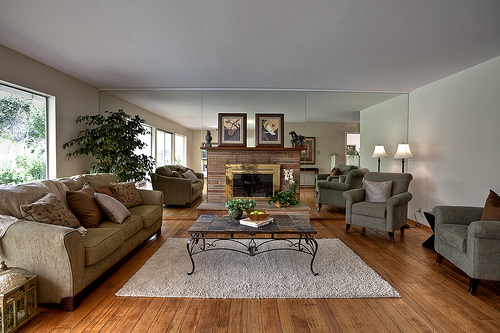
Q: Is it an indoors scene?
A: Yes, it is indoors.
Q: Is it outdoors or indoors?
A: It is indoors.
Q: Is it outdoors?
A: No, it is indoors.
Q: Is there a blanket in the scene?
A: No, there are no blankets.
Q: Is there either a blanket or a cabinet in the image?
A: No, there are no blankets or cabinets.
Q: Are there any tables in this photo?
A: Yes, there is a table.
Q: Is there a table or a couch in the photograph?
A: Yes, there is a table.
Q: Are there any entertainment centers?
A: No, there are no entertainment centers.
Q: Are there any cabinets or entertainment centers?
A: No, there are no entertainment centers or cabinets.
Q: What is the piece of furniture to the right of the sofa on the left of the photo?
A: The piece of furniture is a table.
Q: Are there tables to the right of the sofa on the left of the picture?
A: Yes, there is a table to the right of the sofa.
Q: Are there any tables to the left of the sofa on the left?
A: No, the table is to the right of the sofa.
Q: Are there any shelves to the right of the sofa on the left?
A: No, there is a table to the right of the sofa.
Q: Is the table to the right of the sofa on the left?
A: Yes, the table is to the right of the sofa.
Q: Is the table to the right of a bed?
A: No, the table is to the right of the sofa.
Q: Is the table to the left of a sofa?
A: No, the table is to the right of a sofa.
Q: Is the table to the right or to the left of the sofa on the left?
A: The table is to the right of the sofa.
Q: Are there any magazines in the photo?
A: No, there are no magazines.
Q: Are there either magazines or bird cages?
A: No, there are no magazines or bird cages.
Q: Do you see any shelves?
A: No, there are no shelves.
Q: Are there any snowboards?
A: No, there are no snowboards.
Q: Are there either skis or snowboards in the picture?
A: No, there are no snowboards or skis.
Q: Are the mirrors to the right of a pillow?
A: Yes, the mirrors are to the right of a pillow.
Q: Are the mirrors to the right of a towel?
A: No, the mirrors are to the right of a pillow.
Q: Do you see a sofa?
A: Yes, there is a sofa.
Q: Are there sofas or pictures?
A: Yes, there is a sofa.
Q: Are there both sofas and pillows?
A: Yes, there are both a sofa and a pillow.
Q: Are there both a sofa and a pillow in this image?
A: Yes, there are both a sofa and a pillow.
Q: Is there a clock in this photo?
A: No, there are no clocks.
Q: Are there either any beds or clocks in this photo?
A: No, there are no clocks or beds.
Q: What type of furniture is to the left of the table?
A: The piece of furniture is a sofa.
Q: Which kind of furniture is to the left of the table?
A: The piece of furniture is a sofa.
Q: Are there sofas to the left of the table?
A: Yes, there is a sofa to the left of the table.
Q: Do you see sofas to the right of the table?
A: No, the sofa is to the left of the table.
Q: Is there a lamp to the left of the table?
A: No, there is a sofa to the left of the table.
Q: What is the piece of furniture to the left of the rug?
A: The piece of furniture is a sofa.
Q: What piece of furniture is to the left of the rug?
A: The piece of furniture is a sofa.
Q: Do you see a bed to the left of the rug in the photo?
A: No, there is a sofa to the left of the rug.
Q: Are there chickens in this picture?
A: No, there are no chickens.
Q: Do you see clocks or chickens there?
A: No, there are no chickens or clocks.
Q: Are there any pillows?
A: Yes, there is a pillow.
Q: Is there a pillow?
A: Yes, there is a pillow.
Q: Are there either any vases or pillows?
A: Yes, there is a pillow.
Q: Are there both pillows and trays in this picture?
A: No, there is a pillow but no trays.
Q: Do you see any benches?
A: No, there are no benches.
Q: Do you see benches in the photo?
A: No, there are no benches.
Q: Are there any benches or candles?
A: No, there are no benches or candles.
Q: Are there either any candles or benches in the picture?
A: No, there are no benches or candles.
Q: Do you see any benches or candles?
A: No, there are no benches or candles.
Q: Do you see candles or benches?
A: No, there are no benches or candles.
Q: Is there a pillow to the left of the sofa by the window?
A: Yes, there is a pillow to the left of the sofa.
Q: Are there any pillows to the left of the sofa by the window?
A: Yes, there is a pillow to the left of the sofa.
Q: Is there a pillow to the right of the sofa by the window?
A: No, the pillow is to the left of the sofa.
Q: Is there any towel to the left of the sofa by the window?
A: No, there is a pillow to the left of the sofa.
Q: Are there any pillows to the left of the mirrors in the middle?
A: Yes, there is a pillow to the left of the mirrors.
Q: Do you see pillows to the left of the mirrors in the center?
A: Yes, there is a pillow to the left of the mirrors.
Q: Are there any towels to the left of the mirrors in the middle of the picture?
A: No, there is a pillow to the left of the mirrors.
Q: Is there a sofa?
A: Yes, there is a sofa.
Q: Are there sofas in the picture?
A: Yes, there is a sofa.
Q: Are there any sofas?
A: Yes, there is a sofa.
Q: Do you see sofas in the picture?
A: Yes, there is a sofa.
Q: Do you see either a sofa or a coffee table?
A: Yes, there is a sofa.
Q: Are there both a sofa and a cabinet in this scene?
A: No, there is a sofa but no cabinets.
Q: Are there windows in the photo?
A: Yes, there is a window.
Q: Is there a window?
A: Yes, there is a window.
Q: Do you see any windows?
A: Yes, there is a window.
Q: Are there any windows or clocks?
A: Yes, there is a window.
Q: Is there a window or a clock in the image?
A: Yes, there is a window.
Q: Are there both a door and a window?
A: No, there is a window but no doors.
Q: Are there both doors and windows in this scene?
A: No, there is a window but no doors.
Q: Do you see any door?
A: No, there are no doors.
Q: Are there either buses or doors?
A: No, there are no doors or buses.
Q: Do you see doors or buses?
A: No, there are no doors or buses.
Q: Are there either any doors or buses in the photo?
A: No, there are no doors or buses.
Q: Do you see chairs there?
A: Yes, there is a chair.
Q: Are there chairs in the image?
A: Yes, there is a chair.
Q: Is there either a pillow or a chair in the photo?
A: Yes, there is a chair.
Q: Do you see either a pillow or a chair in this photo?
A: Yes, there is a chair.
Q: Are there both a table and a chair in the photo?
A: Yes, there are both a chair and a table.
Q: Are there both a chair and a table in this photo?
A: Yes, there are both a chair and a table.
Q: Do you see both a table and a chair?
A: Yes, there are both a chair and a table.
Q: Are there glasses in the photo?
A: No, there are no glasses.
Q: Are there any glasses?
A: No, there are no glasses.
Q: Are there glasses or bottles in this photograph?
A: No, there are no glasses or bottles.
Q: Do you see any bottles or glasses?
A: No, there are no glasses or bottles.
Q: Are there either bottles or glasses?
A: No, there are no glasses or bottles.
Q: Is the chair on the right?
A: Yes, the chair is on the right of the image.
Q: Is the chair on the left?
A: No, the chair is on the right of the image.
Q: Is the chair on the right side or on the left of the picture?
A: The chair is on the right of the image.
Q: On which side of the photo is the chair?
A: The chair is on the right of the image.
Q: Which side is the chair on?
A: The chair is on the right of the image.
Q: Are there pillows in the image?
A: Yes, there is a pillow.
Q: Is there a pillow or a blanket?
A: Yes, there is a pillow.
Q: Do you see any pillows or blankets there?
A: Yes, there is a pillow.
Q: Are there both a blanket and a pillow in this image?
A: No, there is a pillow but no blankets.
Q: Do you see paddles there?
A: No, there are no paddles.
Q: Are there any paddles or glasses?
A: No, there are no paddles or glasses.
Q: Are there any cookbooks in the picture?
A: No, there are no cookbooks.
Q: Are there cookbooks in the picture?
A: No, there are no cookbooks.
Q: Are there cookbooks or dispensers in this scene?
A: No, there are no cookbooks or dispensers.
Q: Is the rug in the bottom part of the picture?
A: Yes, the rug is in the bottom of the image.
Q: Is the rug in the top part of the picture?
A: No, the rug is in the bottom of the image.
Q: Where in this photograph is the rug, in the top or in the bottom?
A: The rug is in the bottom of the image.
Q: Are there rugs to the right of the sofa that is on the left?
A: Yes, there is a rug to the right of the sofa.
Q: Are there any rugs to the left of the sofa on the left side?
A: No, the rug is to the right of the sofa.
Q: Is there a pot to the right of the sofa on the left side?
A: No, there is a rug to the right of the sofa.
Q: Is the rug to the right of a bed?
A: No, the rug is to the right of the sofa.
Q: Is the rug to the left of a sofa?
A: No, the rug is to the right of a sofa.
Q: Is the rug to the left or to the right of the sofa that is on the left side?
A: The rug is to the right of the sofa.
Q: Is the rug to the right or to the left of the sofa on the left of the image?
A: The rug is to the right of the sofa.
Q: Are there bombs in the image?
A: No, there are no bombs.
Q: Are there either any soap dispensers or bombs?
A: No, there are no bombs or soap dispensers.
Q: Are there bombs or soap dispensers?
A: No, there are no bombs or soap dispensers.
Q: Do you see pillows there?
A: Yes, there is a pillow.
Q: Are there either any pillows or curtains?
A: Yes, there is a pillow.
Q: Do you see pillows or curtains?
A: Yes, there is a pillow.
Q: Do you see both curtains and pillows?
A: No, there is a pillow but no curtains.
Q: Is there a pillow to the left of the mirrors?
A: Yes, there is a pillow to the left of the mirrors.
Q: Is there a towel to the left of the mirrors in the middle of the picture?
A: No, there is a pillow to the left of the mirrors.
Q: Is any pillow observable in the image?
A: Yes, there is a pillow.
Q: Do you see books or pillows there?
A: Yes, there is a pillow.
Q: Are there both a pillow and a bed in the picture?
A: No, there is a pillow but no beds.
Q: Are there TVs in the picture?
A: No, there are no tvs.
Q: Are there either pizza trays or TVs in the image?
A: No, there are no TVs or pizza trays.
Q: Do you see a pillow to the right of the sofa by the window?
A: No, the pillow is to the left of the sofa.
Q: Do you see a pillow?
A: Yes, there is a pillow.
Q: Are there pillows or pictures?
A: Yes, there is a pillow.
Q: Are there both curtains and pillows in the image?
A: No, there is a pillow but no curtains.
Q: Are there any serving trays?
A: No, there are no serving trays.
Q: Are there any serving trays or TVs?
A: No, there are no serving trays or tvs.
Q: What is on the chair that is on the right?
A: The pillow is on the chair.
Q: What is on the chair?
A: The pillow is on the chair.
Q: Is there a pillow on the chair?
A: Yes, there is a pillow on the chair.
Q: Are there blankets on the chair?
A: No, there is a pillow on the chair.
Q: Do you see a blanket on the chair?
A: No, there is a pillow on the chair.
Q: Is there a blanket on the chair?
A: No, there is a pillow on the chair.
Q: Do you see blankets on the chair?
A: No, there is a pillow on the chair.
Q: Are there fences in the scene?
A: No, there are no fences.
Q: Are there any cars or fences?
A: No, there are no fences or cars.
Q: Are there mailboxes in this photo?
A: No, there are no mailboxes.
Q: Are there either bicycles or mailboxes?
A: No, there are no mailboxes or bicycles.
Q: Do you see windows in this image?
A: Yes, there is a window.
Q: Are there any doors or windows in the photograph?
A: Yes, there is a window.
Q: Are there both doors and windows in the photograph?
A: No, there is a window but no doors.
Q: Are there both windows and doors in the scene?
A: No, there is a window but no doors.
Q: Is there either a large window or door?
A: Yes, there is a large window.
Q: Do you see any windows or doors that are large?
A: Yes, the window is large.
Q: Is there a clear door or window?
A: Yes, there is a clear window.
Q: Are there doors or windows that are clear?
A: Yes, the window is clear.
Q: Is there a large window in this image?
A: Yes, there is a large window.